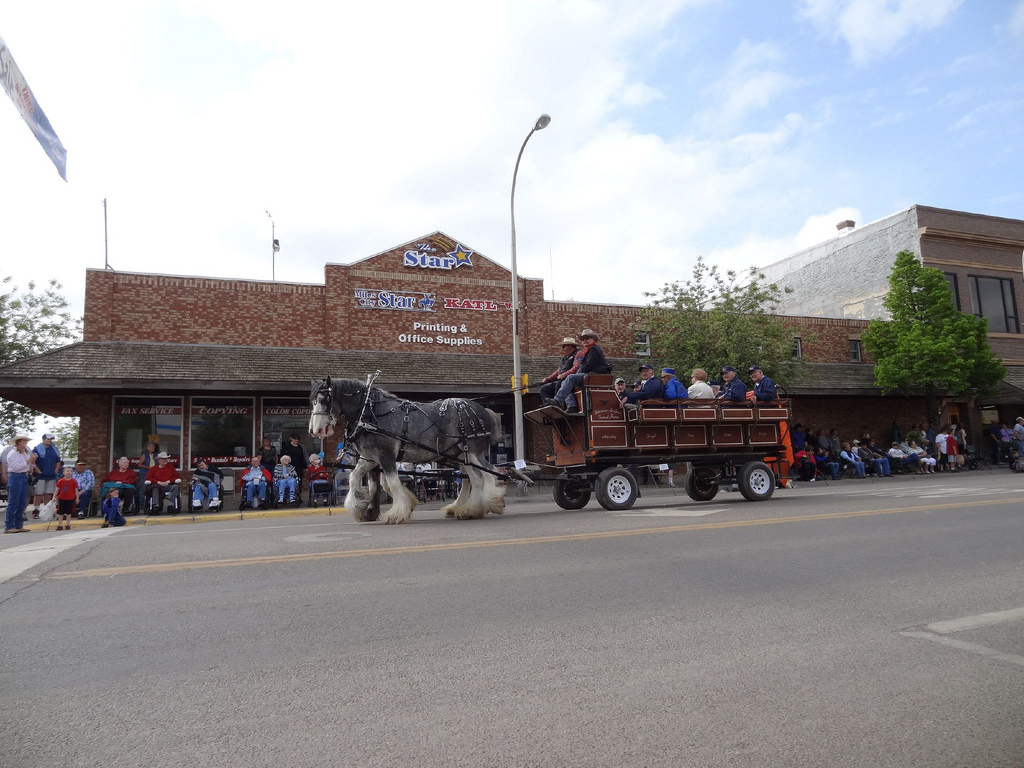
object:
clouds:
[49, 7, 378, 172]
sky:
[0, 0, 1008, 196]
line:
[169, 547, 342, 580]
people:
[544, 328, 612, 412]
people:
[102, 456, 138, 513]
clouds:
[206, 100, 244, 133]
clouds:
[318, 165, 409, 230]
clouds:
[364, 70, 460, 144]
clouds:
[595, 61, 666, 109]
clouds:
[640, 90, 683, 149]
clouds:
[640, 213, 695, 252]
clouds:
[728, 39, 827, 134]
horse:
[306, 376, 504, 523]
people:
[619, 365, 665, 409]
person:
[2, 423, 34, 534]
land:
[0, 577, 1019, 765]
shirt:
[6, 431, 41, 484]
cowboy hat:
[6, 432, 28, 441]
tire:
[595, 469, 638, 510]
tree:
[860, 250, 1003, 466]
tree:
[657, 269, 815, 364]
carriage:
[525, 371, 794, 510]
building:
[0, 227, 948, 516]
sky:
[803, 35, 924, 187]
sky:
[792, 73, 978, 207]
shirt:
[147, 466, 179, 485]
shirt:
[625, 375, 661, 405]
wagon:
[523, 371, 792, 467]